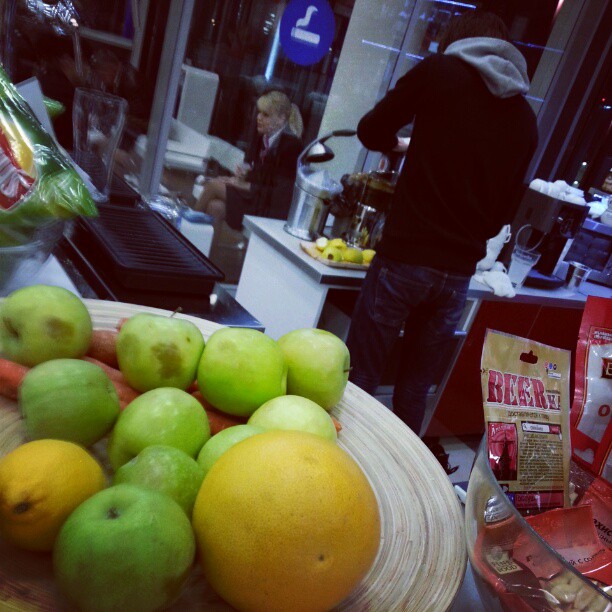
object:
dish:
[3, 285, 467, 611]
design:
[486, 368, 563, 411]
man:
[345, 14, 540, 434]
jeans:
[347, 246, 470, 437]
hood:
[443, 35, 531, 99]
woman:
[193, 90, 304, 264]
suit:
[225, 132, 301, 231]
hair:
[255, 90, 304, 138]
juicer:
[282, 128, 358, 242]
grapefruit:
[188, 426, 380, 609]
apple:
[0, 280, 91, 369]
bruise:
[39, 311, 80, 349]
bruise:
[150, 340, 187, 380]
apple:
[113, 308, 204, 391]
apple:
[52, 485, 197, 608]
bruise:
[151, 546, 192, 599]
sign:
[276, 0, 335, 66]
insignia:
[281, 126, 301, 137]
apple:
[280, 327, 353, 409]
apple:
[109, 384, 211, 475]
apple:
[117, 438, 206, 519]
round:
[277, 0, 335, 68]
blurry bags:
[0, 60, 104, 251]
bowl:
[0, 213, 65, 299]